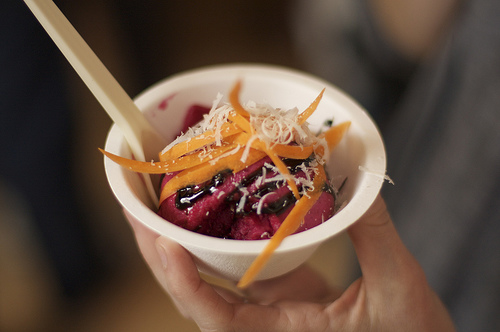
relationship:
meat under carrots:
[157, 174, 334, 241] [99, 79, 349, 286]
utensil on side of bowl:
[23, 1, 169, 211] [102, 62, 386, 282]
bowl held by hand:
[102, 62, 386, 282] [122, 201, 457, 332]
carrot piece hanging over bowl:
[236, 165, 326, 287] [102, 62, 386, 282]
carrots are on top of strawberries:
[99, 79, 349, 286] [184, 154, 267, 230]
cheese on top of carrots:
[161, 95, 298, 155] [99, 79, 349, 286]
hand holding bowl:
[122, 201, 457, 332] [102, 62, 386, 282]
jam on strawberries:
[176, 156, 312, 211] [184, 154, 267, 230]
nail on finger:
[154, 243, 168, 271] [154, 236, 286, 332]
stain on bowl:
[154, 93, 175, 113] [102, 62, 386, 282]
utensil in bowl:
[23, 1, 169, 211] [102, 62, 386, 282]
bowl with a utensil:
[102, 62, 386, 282] [23, 1, 169, 211]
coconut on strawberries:
[162, 93, 330, 192] [184, 154, 267, 230]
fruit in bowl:
[98, 79, 348, 286] [102, 62, 386, 282]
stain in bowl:
[154, 93, 175, 113] [102, 62, 386, 282]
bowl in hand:
[102, 62, 386, 282] [122, 201, 457, 332]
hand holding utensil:
[122, 201, 457, 332] [23, 1, 169, 211]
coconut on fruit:
[162, 93, 330, 192] [98, 79, 348, 286]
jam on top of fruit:
[176, 156, 312, 211] [98, 79, 348, 286]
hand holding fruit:
[122, 201, 457, 332] [98, 79, 348, 286]